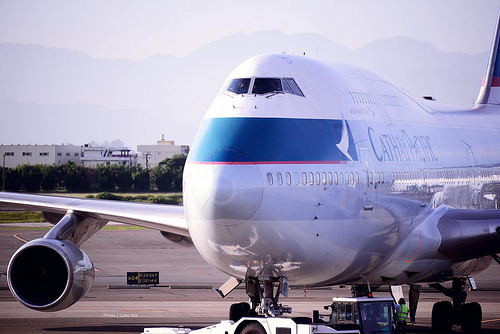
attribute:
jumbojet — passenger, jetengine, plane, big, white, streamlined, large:
[1, 42, 496, 319]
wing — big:
[0, 189, 187, 254]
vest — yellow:
[401, 304, 413, 323]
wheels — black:
[420, 296, 486, 329]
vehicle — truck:
[323, 291, 397, 332]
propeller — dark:
[16, 238, 65, 305]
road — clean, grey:
[93, 234, 178, 273]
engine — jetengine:
[4, 237, 94, 314]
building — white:
[4, 143, 84, 171]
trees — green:
[13, 162, 187, 193]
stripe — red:
[193, 160, 345, 164]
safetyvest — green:
[399, 308, 410, 320]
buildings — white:
[1, 143, 135, 157]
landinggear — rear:
[429, 303, 490, 331]